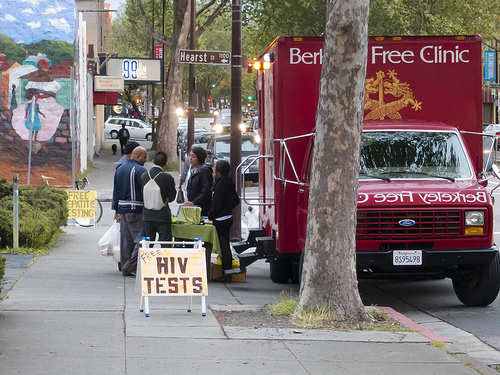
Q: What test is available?
A: HIV test.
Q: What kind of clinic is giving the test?
A: Free clinic.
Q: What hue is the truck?
A: Red.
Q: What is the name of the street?
A: Hearst.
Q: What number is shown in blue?
A: Ninety nine.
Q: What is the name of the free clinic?
A: Berkeley Free Clinic.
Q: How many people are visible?
A: Six.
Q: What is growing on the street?
A: Tree.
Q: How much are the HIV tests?
A: Free.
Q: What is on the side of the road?
A: A red truck.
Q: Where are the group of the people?
A: In front of the red truck.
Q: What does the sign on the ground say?
A: HIV Test.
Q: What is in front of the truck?
A: A tree.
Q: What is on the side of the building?
A: A mural.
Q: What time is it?
A: Afternoon.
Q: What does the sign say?
A: Free HIV tests.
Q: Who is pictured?
A: Medical workers and people speaking with them.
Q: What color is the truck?
A: Red.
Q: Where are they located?
A: On a sidewalk.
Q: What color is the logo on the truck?
A: Yellow.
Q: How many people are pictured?
A: 6.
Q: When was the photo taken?
A: Daylight hours.